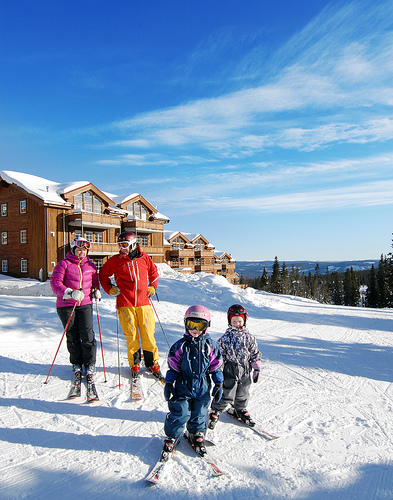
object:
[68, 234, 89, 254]
helmet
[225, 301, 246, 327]
helmet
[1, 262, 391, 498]
snow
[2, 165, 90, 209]
snow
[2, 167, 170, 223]
roof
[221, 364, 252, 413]
pants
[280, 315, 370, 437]
ground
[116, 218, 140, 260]
helmet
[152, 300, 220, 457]
child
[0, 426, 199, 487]
reflection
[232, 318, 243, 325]
eyes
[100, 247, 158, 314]
coat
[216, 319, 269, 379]
coat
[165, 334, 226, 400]
coat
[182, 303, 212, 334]
head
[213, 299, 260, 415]
person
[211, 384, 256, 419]
boots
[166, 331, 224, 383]
jacket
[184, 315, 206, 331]
goggles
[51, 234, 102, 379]
person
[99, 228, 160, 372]
person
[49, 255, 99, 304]
jacket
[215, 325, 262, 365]
jacket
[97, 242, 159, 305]
jacket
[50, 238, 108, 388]
woman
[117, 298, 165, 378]
snowpants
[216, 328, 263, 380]
gray jacket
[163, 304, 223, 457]
person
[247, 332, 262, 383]
arm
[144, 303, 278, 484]
two children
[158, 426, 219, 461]
boots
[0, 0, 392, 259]
sky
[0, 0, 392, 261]
clouds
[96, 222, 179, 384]
skiier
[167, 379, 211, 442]
pants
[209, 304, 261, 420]
boy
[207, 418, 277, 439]
skis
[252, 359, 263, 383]
hand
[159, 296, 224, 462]
person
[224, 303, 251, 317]
goggles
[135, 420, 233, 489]
skis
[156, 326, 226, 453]
snowsuit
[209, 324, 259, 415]
snowsuit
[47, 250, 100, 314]
coat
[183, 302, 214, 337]
helmet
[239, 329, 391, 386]
shadow